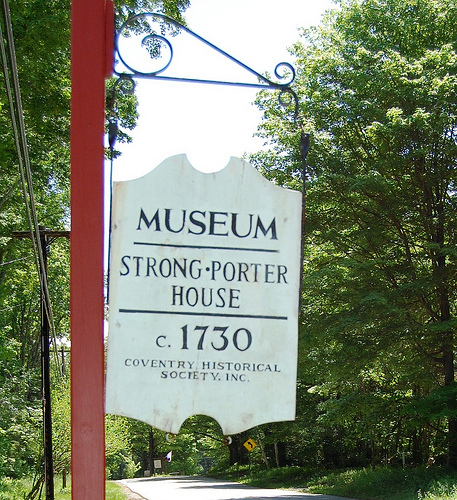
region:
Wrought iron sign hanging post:
[112, 7, 305, 125]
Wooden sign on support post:
[105, 152, 304, 433]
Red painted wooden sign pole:
[68, 0, 112, 498]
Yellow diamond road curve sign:
[239, 435, 259, 451]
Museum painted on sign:
[134, 205, 282, 240]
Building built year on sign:
[155, 322, 252, 352]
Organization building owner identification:
[118, 356, 283, 383]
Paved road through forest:
[112, 477, 362, 499]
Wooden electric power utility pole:
[12, 222, 71, 498]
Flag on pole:
[164, 448, 173, 462]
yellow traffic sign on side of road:
[235, 434, 262, 458]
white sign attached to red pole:
[79, 135, 317, 453]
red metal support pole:
[55, 0, 122, 498]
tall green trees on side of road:
[220, 1, 455, 488]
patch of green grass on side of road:
[221, 453, 453, 498]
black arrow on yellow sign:
[242, 437, 256, 452]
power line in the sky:
[2, 3, 71, 382]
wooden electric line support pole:
[3, 218, 72, 498]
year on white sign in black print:
[131, 317, 259, 358]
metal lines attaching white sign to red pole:
[107, 5, 321, 197]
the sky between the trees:
[134, 32, 264, 122]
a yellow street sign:
[242, 435, 261, 470]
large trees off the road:
[316, 209, 455, 425]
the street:
[116, 446, 216, 492]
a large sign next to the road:
[75, 29, 297, 483]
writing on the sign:
[129, 207, 259, 387]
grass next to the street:
[275, 462, 447, 493]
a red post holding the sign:
[70, 323, 101, 492]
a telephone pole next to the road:
[28, 234, 62, 495]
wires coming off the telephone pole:
[16, 207, 76, 351]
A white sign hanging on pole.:
[104, 153, 303, 435]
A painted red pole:
[69, 1, 114, 499]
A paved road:
[120, 476, 355, 498]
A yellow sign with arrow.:
[241, 436, 257, 452]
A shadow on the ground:
[180, 482, 275, 495]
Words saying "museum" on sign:
[134, 206, 278, 241]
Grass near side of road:
[205, 462, 456, 498]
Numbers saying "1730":
[177, 324, 251, 350]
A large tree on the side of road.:
[238, 0, 454, 473]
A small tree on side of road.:
[16, 368, 134, 489]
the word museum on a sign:
[138, 204, 279, 239]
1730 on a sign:
[176, 322, 252, 351]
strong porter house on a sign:
[116, 248, 289, 311]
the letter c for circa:
[149, 332, 173, 348]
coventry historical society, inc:
[118, 354, 281, 384]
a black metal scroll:
[113, 12, 301, 85]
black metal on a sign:
[101, 68, 316, 190]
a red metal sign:
[71, 0, 110, 498]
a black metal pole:
[2, 230, 69, 498]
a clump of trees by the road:
[261, 0, 454, 467]